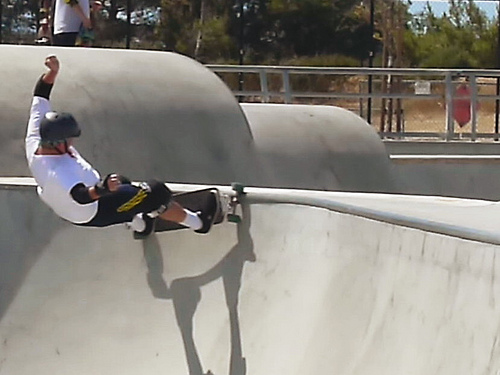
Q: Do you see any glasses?
A: No, there are no glasses.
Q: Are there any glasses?
A: No, there are no glasses.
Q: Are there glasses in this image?
A: No, there are no glasses.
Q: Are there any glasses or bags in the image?
A: No, there are no glasses or bags.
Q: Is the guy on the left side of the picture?
A: Yes, the guy is on the left of the image.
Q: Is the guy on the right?
A: No, the guy is on the left of the image.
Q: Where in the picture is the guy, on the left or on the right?
A: The guy is on the left of the image.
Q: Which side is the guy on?
A: The guy is on the left of the image.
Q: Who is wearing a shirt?
A: The guy is wearing a shirt.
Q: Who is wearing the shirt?
A: The guy is wearing a shirt.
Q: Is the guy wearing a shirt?
A: Yes, the guy is wearing a shirt.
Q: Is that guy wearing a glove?
A: No, the guy is wearing a shirt.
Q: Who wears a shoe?
A: The guy wears a shoe.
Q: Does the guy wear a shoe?
A: Yes, the guy wears a shoe.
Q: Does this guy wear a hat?
A: No, the guy wears a shoe.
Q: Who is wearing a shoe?
A: The guy is wearing a shoe.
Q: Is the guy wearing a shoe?
A: Yes, the guy is wearing a shoe.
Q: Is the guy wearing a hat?
A: No, the guy is wearing a shoe.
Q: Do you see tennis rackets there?
A: No, there are no tennis rackets.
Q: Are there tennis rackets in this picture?
A: No, there are no tennis rackets.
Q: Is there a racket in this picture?
A: No, there are no rackets.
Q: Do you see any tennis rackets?
A: No, there are no tennis rackets.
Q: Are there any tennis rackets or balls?
A: No, there are no tennis rackets or balls.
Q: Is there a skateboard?
A: Yes, there is a skateboard.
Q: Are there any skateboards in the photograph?
A: Yes, there is a skateboard.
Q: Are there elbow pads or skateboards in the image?
A: Yes, there is a skateboard.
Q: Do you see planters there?
A: No, there are no planters.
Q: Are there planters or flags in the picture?
A: No, there are no planters or flags.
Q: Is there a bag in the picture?
A: No, there are no bags.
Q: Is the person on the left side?
A: Yes, the person is on the left of the image.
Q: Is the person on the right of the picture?
A: No, the person is on the left of the image.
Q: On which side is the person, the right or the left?
A: The person is on the left of the image.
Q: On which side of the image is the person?
A: The person is on the left of the image.